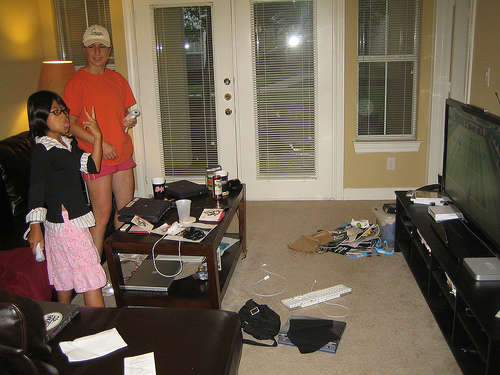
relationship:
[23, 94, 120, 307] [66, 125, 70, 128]
girl sticking out tounge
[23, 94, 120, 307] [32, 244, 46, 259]
girl holding wii remote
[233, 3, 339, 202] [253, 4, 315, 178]
blinds on door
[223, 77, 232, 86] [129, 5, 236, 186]
locks on door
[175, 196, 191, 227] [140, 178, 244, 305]
cup on table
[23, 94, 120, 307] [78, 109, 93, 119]
girl with finger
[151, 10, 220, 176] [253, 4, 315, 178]
window on door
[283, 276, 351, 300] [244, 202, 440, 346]
keyboard on floor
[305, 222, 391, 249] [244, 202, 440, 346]
pile on floor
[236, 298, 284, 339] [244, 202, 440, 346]
bags on floor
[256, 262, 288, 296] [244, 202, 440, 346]
cord on floor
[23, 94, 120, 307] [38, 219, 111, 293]
girl wearing skirt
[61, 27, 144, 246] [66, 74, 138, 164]
woman wearing shirt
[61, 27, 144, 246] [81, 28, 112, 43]
woman wearing hat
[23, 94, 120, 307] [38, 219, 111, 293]
girl in skirt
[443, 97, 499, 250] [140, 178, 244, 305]
tv on table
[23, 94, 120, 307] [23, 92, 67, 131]
girl with hair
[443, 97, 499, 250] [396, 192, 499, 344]
tv on table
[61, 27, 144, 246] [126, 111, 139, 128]
woman holding wii remote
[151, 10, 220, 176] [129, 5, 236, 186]
window on door